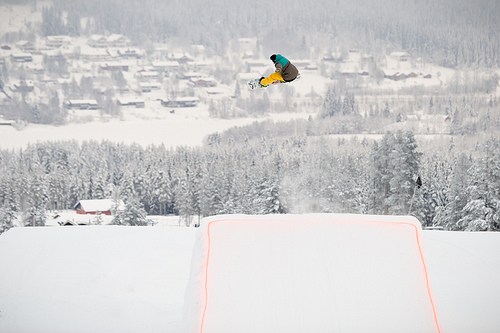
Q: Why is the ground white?
A: Covered in snow.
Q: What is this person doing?
A: Snowboarding.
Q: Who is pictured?
A: A snowboarder.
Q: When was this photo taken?
A: During the daytime.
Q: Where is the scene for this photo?
A: A ski slope.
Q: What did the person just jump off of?
A: A ramp.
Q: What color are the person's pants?
A: Yellow.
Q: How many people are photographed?
A: One.